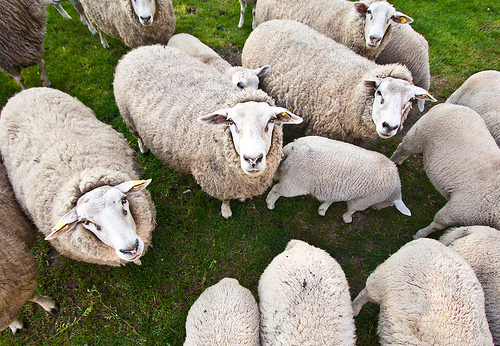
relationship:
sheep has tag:
[99, 35, 308, 221] [219, 110, 232, 120]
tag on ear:
[219, 110, 232, 120] [193, 90, 243, 133]